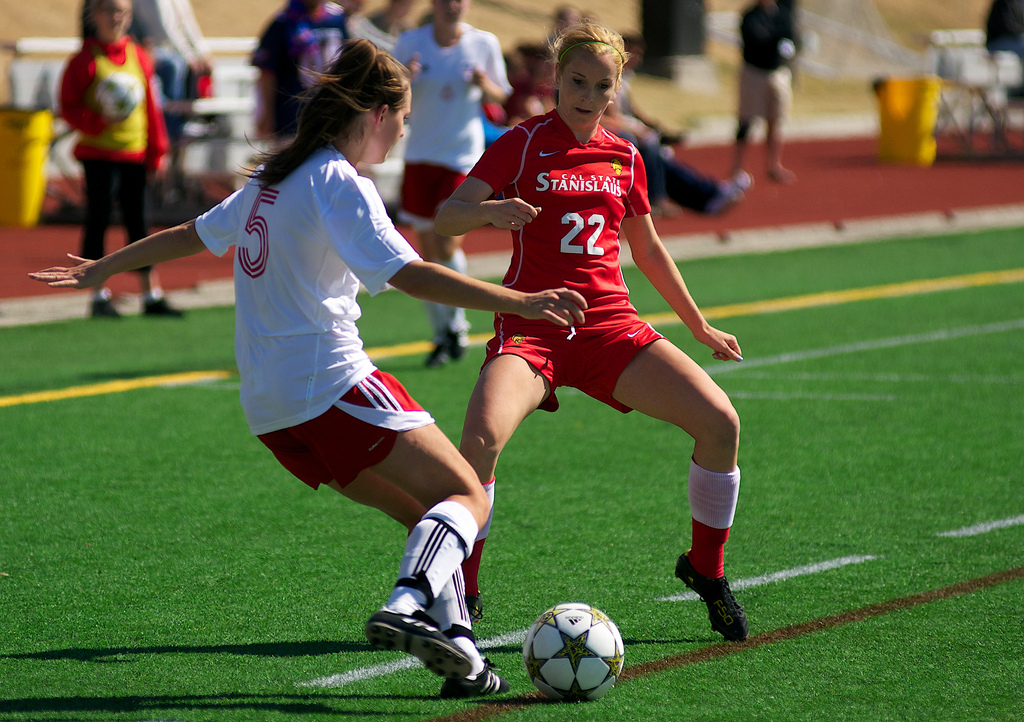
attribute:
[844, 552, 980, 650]
line — red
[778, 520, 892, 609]
line — white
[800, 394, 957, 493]
greengrass — grass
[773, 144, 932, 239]
redground — red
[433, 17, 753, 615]
female — soccer player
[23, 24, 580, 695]
female — soccer player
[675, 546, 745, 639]
shoe — BLACK, soccer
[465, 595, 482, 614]
shoe — black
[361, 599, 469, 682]
shoe — black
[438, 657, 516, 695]
shoe — black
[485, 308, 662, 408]
shorts — red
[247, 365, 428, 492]
shorts — red, white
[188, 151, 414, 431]
jersey — white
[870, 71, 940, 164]
bin — big, yellow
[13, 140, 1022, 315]
ground — red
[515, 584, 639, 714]
ball — star covered